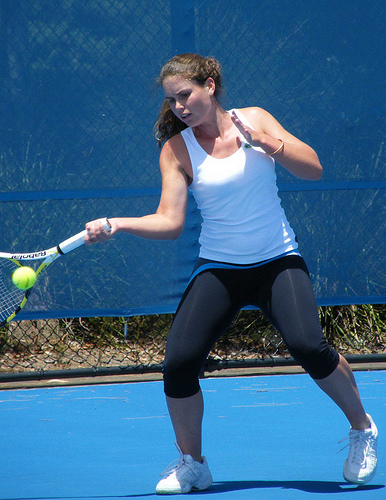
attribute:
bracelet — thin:
[269, 133, 283, 156]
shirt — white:
[177, 105, 301, 263]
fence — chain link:
[2, 2, 383, 346]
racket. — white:
[7, 181, 106, 353]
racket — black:
[0, 215, 116, 326]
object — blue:
[9, 4, 377, 311]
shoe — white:
[154, 440, 215, 494]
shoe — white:
[336, 410, 379, 485]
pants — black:
[136, 246, 358, 401]